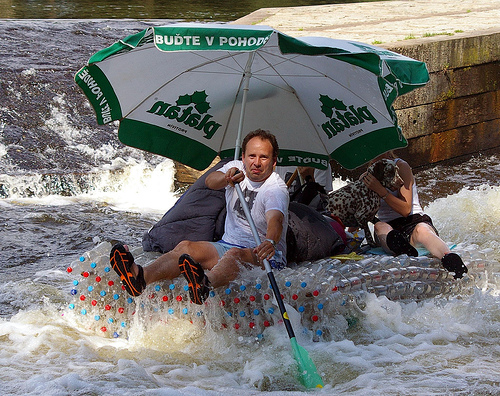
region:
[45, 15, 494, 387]
a family is rafting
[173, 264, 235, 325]
his shoes are black and orange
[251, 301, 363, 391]
the paddle is green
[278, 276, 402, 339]
the raft is made of bottles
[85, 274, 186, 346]
the bottles are clear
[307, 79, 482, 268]
a woman holding a dog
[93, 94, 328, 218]
the umbrella is green and white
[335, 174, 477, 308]
she has black shoes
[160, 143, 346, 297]
his shirt is white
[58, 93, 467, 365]
they are rafting together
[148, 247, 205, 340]
bottom of a shoe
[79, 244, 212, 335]
two orange and black shoes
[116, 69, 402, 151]
green and white umbrella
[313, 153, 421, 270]
brown and white speckled dog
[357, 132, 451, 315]
person on a raft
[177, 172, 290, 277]
white t shirt with gray graphic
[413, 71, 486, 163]
large bricks with green moss growing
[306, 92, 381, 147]
green letters on white back ground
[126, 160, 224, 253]
a gray sleeping bag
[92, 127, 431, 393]
two people on a raft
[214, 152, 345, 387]
The man has a paddle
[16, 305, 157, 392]
The water is raging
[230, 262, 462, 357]
The raft is made of soda bottles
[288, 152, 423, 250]
The person is holding the dog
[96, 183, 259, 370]
The man has sandals on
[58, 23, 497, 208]
The umbrella is white and green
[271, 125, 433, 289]
The people are sitting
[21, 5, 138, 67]
The water in the back is calm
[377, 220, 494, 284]
The woman has flip flops on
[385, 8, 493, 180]
The wall in the back is brick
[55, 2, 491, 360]
a guy rowing his rubber raft with dog and family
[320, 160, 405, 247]
a hunting dog in a white raft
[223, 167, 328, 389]
a man holding a green ore and pushing against the white caps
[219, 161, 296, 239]
a man in a white shirt holding a green ore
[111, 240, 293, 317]
a man wearing blue shorts and wearing black and orange tennis shoes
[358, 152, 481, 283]
a person holding dog inside the rubber raft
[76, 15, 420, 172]
a green and yellow umbrella to protect from sun and water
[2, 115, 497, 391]
water is full of white caps pushing the raft back to shore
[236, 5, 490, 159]
a brown brick structure on shore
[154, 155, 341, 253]
a grey sleeping bag is behind the man rowing with one ore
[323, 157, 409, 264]
a brown and white dog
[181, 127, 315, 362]
a man rafting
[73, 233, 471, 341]
a polka dotted raft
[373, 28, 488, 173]
a tan brick wall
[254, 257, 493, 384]
water rapids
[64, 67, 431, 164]
a green and white umbrella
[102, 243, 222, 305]
orange and black sandals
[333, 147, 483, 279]
man sitting with a dog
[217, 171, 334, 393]
a green and gray paddle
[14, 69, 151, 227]
a small waterfall